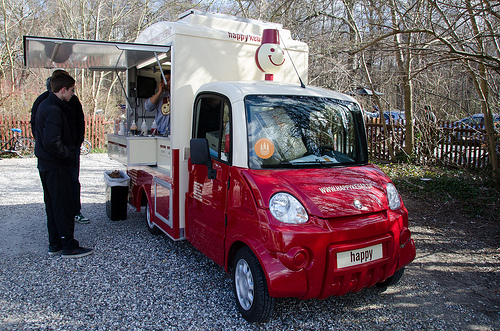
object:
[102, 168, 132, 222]
garbage can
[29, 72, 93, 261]
man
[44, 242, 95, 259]
shoes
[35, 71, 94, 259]
man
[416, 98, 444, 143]
man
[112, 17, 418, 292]
small truck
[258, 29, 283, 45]
red hat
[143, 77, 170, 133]
man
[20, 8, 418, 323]
truck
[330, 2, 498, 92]
trees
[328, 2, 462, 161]
bare tree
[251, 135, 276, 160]
decal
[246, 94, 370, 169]
windshield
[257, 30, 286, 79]
doll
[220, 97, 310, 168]
boxes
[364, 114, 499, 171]
fence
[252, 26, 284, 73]
round head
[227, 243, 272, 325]
tire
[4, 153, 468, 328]
pebbles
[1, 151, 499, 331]
ground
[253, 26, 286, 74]
smiley face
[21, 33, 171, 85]
side door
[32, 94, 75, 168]
shirt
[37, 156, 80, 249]
pants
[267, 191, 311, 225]
headlight